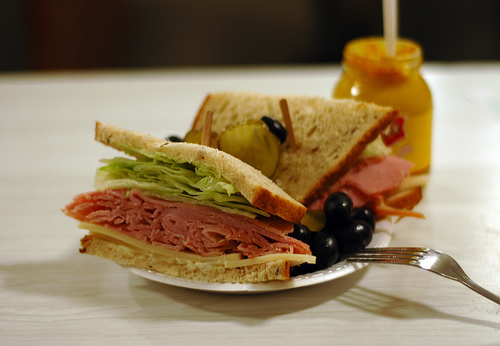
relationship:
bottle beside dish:
[333, 37, 436, 194] [122, 213, 398, 297]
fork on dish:
[346, 242, 499, 306] [120, 214, 394, 294]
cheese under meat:
[77, 221, 317, 263] [60, 187, 314, 258]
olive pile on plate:
[285, 189, 381, 277] [101, 195, 393, 297]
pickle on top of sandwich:
[217, 117, 279, 154] [82, 105, 315, 279]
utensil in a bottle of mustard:
[376, 2, 401, 58] [329, 35, 437, 203]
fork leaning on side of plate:
[346, 242, 498, 310] [80, 137, 425, 297]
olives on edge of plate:
[290, 192, 380, 275] [104, 224, 406, 295]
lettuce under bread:
[93, 147, 237, 211] [88, 120, 308, 222]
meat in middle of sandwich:
[78, 189, 294, 266] [134, 110, 304, 300]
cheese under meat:
[244, 242, 305, 325] [79, 191, 318, 269]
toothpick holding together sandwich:
[200, 110, 213, 147] [59, 120, 317, 282]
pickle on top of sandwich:
[216, 116, 283, 177] [56, 69, 416, 309]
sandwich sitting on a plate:
[58, 119, 317, 286] [211, 250, 344, 346]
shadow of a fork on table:
[348, 287, 463, 326] [2, 300, 494, 342]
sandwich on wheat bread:
[58, 111, 310, 287] [94, 93, 420, 283]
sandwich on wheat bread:
[58, 111, 310, 287] [61, 90, 419, 278]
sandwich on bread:
[182, 82, 420, 222] [89, 119, 306, 223]